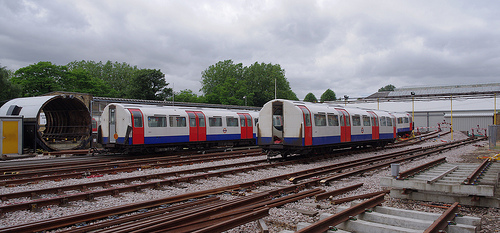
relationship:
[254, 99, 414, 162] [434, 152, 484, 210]
cars waiting for passengers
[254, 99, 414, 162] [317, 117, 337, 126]
cars carrying vacationers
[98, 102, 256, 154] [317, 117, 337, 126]
train carrying vacationers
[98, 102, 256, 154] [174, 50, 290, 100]
train close to trees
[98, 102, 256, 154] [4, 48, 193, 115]
train close to trees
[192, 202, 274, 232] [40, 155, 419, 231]
metal rails for tracks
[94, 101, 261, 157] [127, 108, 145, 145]
train has car door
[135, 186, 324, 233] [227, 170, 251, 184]
tracks has gravel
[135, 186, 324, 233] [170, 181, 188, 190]
tracks has wood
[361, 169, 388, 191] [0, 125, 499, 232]
gravel under train tracks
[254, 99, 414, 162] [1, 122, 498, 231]
cars in station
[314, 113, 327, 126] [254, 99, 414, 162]
window on cars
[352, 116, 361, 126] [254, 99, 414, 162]
window on cars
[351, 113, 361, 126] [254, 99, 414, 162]
window on cars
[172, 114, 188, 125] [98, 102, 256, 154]
window on train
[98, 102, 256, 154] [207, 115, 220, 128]
train has window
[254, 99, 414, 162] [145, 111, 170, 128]
cars has window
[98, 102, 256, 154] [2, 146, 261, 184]
train on tracks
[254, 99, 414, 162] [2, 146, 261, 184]
cars on tracks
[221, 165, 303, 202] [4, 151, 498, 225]
tracks on ground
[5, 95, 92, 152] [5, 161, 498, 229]
culvert on ground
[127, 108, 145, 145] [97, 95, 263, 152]
car door on train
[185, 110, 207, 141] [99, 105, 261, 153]
car door on train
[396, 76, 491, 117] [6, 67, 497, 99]
buildings on background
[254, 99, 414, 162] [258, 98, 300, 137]
cars has back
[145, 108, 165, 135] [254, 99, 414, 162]
window on cars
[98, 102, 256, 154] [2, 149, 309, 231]
train owned by railroad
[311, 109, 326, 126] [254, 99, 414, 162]
window on a cars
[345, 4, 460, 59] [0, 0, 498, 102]
clouds in sky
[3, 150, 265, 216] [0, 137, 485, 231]
track by or track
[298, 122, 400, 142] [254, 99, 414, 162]
doors on a cars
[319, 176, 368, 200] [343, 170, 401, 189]
rails laying in gravel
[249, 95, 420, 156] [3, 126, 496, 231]
cars on a track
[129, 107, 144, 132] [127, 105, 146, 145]
window in a car door